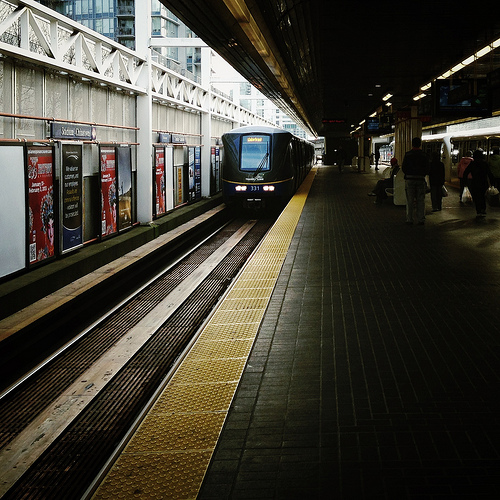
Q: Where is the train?
A: At station.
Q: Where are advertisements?
A: On wall.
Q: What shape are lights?
A: Round.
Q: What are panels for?
A: Advertising space.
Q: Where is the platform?
A: Station.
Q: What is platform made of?
A: Cement.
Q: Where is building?
A: Outside station.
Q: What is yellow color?
A: Line.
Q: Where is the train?
A: On the tracks.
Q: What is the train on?
A: Tracks.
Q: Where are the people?
A: On the platform.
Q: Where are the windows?
A: On the train.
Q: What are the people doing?
A: Waiting for the train.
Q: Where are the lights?
A: On the ceiling.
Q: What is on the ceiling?
A: Lights.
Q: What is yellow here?
A: The platform.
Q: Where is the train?
A: On train tracks.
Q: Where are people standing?
A: On platform.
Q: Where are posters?
A: On the wall.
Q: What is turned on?
A: Train's headlights.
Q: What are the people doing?
A: Waiting for the train.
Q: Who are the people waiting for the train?
A: Men and women.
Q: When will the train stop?
A: When it reaches the platform.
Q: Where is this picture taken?
A: At a train station.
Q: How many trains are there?
A: One.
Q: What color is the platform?
A: Yellow and gray.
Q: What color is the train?
A: Blue, yellow and black.